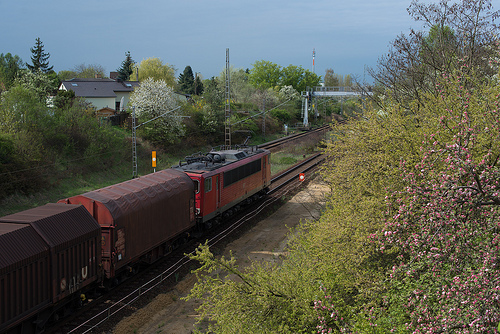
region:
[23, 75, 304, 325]
the train is old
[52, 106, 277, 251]
the train is old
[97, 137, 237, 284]
the train is old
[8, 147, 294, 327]
the train is moving on the tracks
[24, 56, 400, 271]
it is moving through a residential neighborhood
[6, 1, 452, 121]
the sky and seems clear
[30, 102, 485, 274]
there is a lot of green trees surrounding the track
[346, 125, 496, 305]
colorful leaves are growing along the landscape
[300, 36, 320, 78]
small tower like structure in the background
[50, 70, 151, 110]
a white house on the left side of the track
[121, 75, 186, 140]
this tree is white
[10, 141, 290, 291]
this is the caboose of the rain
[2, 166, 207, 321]
the last two cars before the caboose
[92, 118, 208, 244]
the train is rusty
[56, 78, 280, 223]
the train is rusty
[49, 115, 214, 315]
the train is rusty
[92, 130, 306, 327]
the train is rusty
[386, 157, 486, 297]
Pink flowering trees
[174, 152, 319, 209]
Train on tracks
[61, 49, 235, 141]
House near train tracks.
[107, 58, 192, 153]
White flowering tree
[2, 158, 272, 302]
Three train cars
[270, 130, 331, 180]
Two sets of train tracks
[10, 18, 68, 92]
Pine tree against blue sky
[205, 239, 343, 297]
Bushes next to train track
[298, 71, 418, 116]
Walking bridge over train tracks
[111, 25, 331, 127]
Trees blooming in spring time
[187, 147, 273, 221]
a red and black train caboose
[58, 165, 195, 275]
the middle red train car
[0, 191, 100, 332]
the front red train car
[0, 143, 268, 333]
three red train cars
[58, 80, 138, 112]
a house partially hidden behind trees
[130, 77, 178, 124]
a white colored tree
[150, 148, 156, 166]
an orange train sign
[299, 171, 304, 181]
a red train sign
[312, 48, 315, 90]
a tower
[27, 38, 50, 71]
top of a tall tree